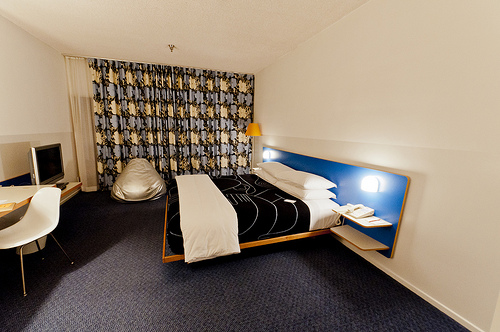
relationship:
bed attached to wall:
[161, 144, 411, 263] [255, 1, 498, 331]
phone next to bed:
[334, 203, 375, 228] [161, 144, 411, 263]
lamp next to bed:
[244, 122, 265, 170] [161, 144, 411, 263]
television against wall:
[32, 143, 66, 188] [2, 16, 85, 185]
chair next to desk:
[0, 187, 75, 300] [0, 183, 56, 228]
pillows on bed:
[253, 162, 336, 201] [161, 144, 411, 263]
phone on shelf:
[334, 203, 375, 228] [335, 207, 393, 230]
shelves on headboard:
[331, 204, 392, 253] [261, 144, 412, 257]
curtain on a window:
[87, 60, 255, 191] [66, 54, 257, 191]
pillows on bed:
[288, 171, 339, 200] [161, 144, 411, 263]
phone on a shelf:
[334, 203, 375, 228] [335, 207, 393, 230]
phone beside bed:
[334, 203, 375, 228] [161, 144, 411, 263]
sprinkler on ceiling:
[167, 43, 177, 53] [0, 1, 358, 84]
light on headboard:
[354, 170, 389, 201] [261, 144, 412, 257]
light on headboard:
[262, 149, 279, 162] [261, 144, 412, 257]